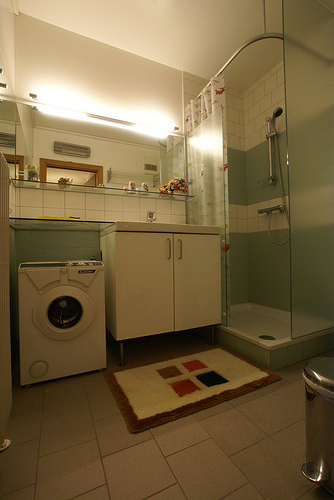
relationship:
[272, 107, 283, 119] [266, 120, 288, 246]
shower with hose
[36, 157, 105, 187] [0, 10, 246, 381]
mirror on wall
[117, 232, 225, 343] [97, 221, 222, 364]
doors on cabinet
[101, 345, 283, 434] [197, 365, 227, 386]
bathmat with square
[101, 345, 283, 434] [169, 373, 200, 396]
bathmat with square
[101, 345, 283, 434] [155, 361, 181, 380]
bathmat with square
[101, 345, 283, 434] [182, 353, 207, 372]
bathmat with square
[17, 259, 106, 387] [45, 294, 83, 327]
appliance with window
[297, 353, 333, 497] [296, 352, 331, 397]
metal can with lid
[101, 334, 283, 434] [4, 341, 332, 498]
bathmat on floor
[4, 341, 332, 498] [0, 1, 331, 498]
floor in bathroom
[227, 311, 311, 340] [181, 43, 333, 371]
floor of shower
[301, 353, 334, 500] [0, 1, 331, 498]
metal can in bathroom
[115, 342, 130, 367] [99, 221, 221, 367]
leg on cabinet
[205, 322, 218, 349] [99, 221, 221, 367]
leg on cabinet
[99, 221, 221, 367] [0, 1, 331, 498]
cabinet in bathroom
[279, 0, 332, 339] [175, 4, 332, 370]
glass door on shower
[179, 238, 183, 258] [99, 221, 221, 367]
handle on cabinet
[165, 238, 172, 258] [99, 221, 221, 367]
handle on cabinet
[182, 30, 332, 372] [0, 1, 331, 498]
shower stall in bathroom